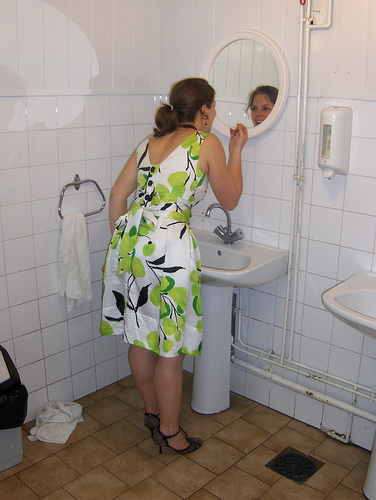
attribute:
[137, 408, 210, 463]
shoes — black, gray, high-heeled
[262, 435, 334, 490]
drain — square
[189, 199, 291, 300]
sink — silver, white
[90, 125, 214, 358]
party dress — cut, flowered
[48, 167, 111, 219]
holder — chrome, silver, metal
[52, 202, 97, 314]
towel — white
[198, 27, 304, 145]
mirror — round, white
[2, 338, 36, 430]
handbag — black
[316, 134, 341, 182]
soap — liquid, white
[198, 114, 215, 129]
earrings — amber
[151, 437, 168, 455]
heel — short